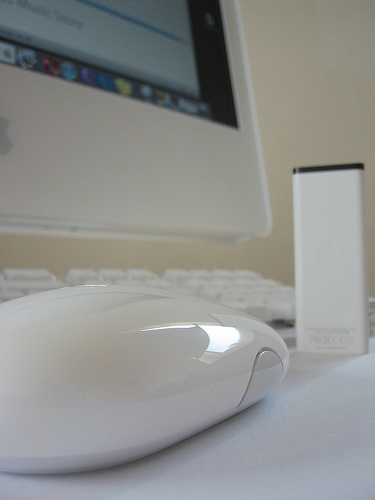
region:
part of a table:
[333, 423, 335, 427]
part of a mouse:
[162, 425, 174, 435]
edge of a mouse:
[115, 367, 124, 377]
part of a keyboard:
[256, 303, 263, 310]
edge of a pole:
[293, 288, 304, 327]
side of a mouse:
[231, 356, 237, 366]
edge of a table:
[261, 425, 265, 435]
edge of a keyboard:
[289, 312, 301, 328]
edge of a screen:
[235, 216, 259, 228]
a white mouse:
[17, 271, 277, 484]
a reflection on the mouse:
[158, 309, 256, 395]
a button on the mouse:
[231, 339, 290, 421]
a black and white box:
[287, 159, 371, 356]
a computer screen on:
[3, 1, 261, 228]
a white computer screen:
[1, 0, 262, 243]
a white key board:
[8, 268, 293, 307]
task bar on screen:
[6, 42, 222, 130]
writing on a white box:
[301, 315, 360, 355]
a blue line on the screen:
[102, 11, 196, 61]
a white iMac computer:
[0, 0, 276, 248]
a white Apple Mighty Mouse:
[0, 283, 290, 476]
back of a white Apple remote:
[290, 163, 368, 354]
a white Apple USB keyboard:
[0, 269, 310, 328]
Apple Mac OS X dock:
[1, 39, 210, 119]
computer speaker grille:
[1, 218, 248, 246]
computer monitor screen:
[0, 0, 238, 128]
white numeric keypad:
[170, 267, 299, 321]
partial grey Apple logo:
[0, 113, 12, 152]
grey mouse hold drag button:
[242, 349, 285, 408]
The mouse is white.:
[18, 272, 292, 480]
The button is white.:
[230, 336, 286, 418]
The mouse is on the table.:
[8, 266, 306, 492]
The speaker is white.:
[288, 155, 374, 362]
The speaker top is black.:
[284, 155, 366, 175]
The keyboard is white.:
[9, 258, 317, 324]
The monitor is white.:
[2, 10, 273, 250]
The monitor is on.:
[22, 0, 236, 123]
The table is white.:
[76, 310, 370, 499]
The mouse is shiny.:
[11, 277, 289, 470]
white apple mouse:
[0, 282, 291, 474]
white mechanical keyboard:
[0, 268, 296, 329]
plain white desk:
[0, 350, 369, 497]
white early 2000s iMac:
[0, 0, 263, 236]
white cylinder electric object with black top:
[289, 158, 364, 353]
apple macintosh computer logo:
[0, 120, 15, 152]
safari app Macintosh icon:
[60, 60, 76, 81]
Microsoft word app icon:
[96, 72, 112, 87]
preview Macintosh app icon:
[15, 45, 33, 66]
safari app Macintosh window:
[0, 0, 198, 94]